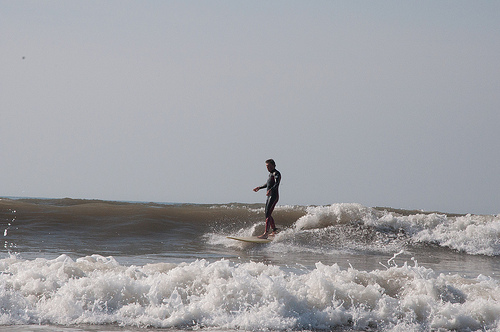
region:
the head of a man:
[261, 154, 281, 174]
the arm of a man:
[270, 167, 283, 191]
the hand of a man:
[249, 179, 261, 195]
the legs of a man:
[261, 195, 278, 233]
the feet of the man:
[253, 225, 283, 240]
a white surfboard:
[223, 225, 290, 249]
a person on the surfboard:
[244, 152, 283, 242]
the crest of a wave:
[1, 191, 498, 228]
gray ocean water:
[0, 193, 499, 330]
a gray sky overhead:
[0, 0, 499, 217]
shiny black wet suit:
[261, 172, 287, 235]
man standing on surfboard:
[246, 156, 285, 247]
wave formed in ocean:
[4, 197, 478, 259]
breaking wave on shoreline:
[3, 253, 490, 330]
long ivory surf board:
[231, 231, 286, 248]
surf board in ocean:
[222, 231, 285, 247]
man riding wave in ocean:
[243, 156, 288, 248]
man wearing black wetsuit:
[243, 156, 283, 238]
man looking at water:
[254, 159, 283, 234]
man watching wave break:
[248, 158, 281, 240]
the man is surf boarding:
[233, 134, 300, 291]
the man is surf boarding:
[240, 128, 388, 328]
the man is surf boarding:
[206, 104, 311, 221]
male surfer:
[254, 155, 289, 228]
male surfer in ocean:
[251, 156, 287, 230]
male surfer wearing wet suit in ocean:
[255, 152, 285, 222]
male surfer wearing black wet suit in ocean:
[254, 172, 289, 217]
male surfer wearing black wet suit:
[252, 174, 285, 213]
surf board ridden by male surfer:
[229, 232, 263, 247]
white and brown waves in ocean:
[29, 247, 142, 317]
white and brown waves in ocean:
[166, 252, 281, 320]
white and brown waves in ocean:
[298, 238, 437, 315]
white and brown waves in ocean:
[318, 197, 476, 278]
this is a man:
[251, 153, 293, 243]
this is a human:
[238, 145, 295, 255]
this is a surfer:
[248, 155, 298, 252]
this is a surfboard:
[213, 219, 289, 255]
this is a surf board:
[222, 214, 297, 259]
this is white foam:
[65, 257, 275, 330]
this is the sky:
[191, 107, 238, 159]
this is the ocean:
[94, 215, 149, 250]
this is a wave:
[46, 197, 101, 246]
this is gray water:
[69, 198, 167, 261]